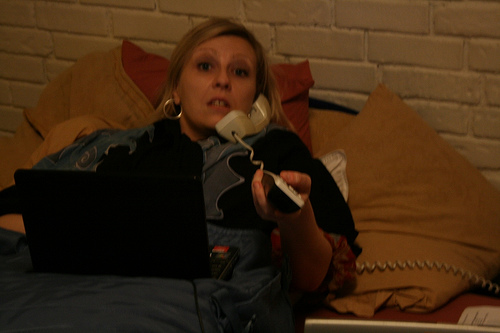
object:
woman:
[0, 15, 363, 333]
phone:
[210, 89, 282, 151]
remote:
[253, 163, 309, 217]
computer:
[11, 160, 237, 280]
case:
[325, 77, 496, 313]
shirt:
[4, 112, 361, 331]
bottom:
[262, 179, 300, 217]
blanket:
[0, 221, 307, 331]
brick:
[365, 29, 467, 68]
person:
[1, 15, 356, 332]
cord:
[236, 125, 495, 306]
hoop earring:
[163, 95, 183, 120]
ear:
[171, 79, 182, 106]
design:
[3, 128, 359, 257]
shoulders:
[216, 129, 356, 239]